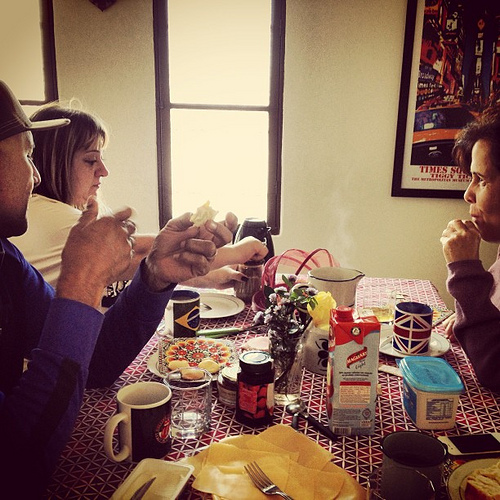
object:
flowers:
[247, 272, 323, 342]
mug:
[390, 299, 434, 357]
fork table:
[242, 460, 295, 498]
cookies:
[197, 357, 220, 372]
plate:
[145, 338, 243, 381]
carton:
[324, 303, 383, 437]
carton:
[399, 352, 464, 429]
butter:
[398, 355, 464, 430]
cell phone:
[436, 433, 499, 458]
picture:
[388, 0, 499, 199]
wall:
[54, 0, 498, 311]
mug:
[105, 378, 173, 464]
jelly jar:
[234, 348, 277, 427]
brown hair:
[29, 96, 107, 208]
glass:
[161, 368, 213, 442]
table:
[0, 273, 499, 499]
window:
[167, 0, 273, 109]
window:
[0, 1, 44, 102]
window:
[169, 110, 267, 226]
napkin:
[284, 459, 346, 499]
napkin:
[184, 440, 292, 499]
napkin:
[246, 424, 333, 470]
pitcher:
[305, 265, 365, 318]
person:
[437, 110, 499, 398]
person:
[4, 96, 267, 298]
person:
[0, 75, 238, 487]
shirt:
[5, 191, 91, 292]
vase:
[267, 330, 307, 407]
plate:
[377, 328, 450, 360]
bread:
[189, 199, 218, 227]